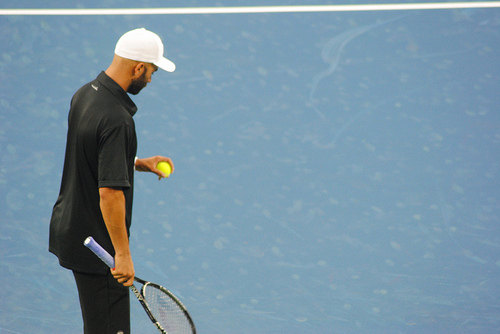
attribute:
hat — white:
[113, 25, 177, 73]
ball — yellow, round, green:
[156, 163, 171, 178]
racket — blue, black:
[82, 235, 196, 334]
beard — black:
[127, 67, 147, 95]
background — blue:
[1, 1, 498, 334]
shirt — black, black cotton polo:
[48, 72, 139, 275]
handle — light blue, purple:
[83, 236, 116, 270]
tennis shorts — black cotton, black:
[72, 269, 132, 334]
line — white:
[1, 3, 498, 16]